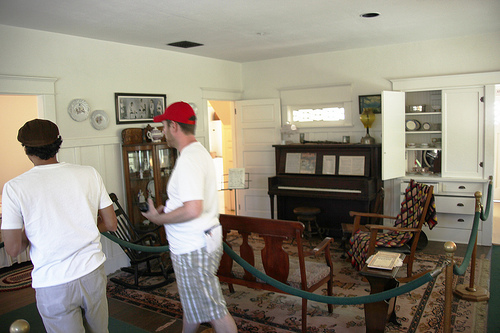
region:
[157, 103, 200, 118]
man has on a red hat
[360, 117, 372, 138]
yellow glass cup on top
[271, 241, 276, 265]
bench is made out of wood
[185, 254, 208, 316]
man wearing some checker shorts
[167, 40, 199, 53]
air vent in the ceiling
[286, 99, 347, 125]
window behind the wooden door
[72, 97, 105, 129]
plates are hanging on the wall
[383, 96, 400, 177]
door to the cabinet is open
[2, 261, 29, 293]
rug is on the floor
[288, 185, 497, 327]
green velvet rope around furniture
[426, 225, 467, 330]
wood posts with gold tops holding rope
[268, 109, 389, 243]
vintage upright piano with stool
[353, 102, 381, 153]
vintage yellow glass kerosene lamp on piano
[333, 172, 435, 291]
wood rocking chair with knitted blanket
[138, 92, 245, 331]
man in red cap and plaid shorts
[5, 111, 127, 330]
back of man in brown hat and white shirt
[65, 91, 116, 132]
vintage china plates hanging on white wall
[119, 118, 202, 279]
wood curio cabinet with glass doors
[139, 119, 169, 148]
vintage china tea kettle with pattern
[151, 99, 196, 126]
man wearing a red cap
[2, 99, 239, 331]
two men standing in a living room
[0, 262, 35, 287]
an oval rug on the floor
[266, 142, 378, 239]
a dark wooden upright piano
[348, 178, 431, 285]
a wooden rocking chair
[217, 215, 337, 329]
a wooden bench with gray cushion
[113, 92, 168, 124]
a framed picture on the wall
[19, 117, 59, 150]
man wearing a round brown hat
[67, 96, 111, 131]
decorative white plates on the wall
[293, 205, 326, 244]
a wooden piano stool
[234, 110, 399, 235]
a brown piano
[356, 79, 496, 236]
a white cupboard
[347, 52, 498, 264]
a white cupboard with dishes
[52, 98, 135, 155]
white plates on the wall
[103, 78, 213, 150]
a picture frame on the wall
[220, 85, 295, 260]
a white wooden door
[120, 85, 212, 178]
a man with a red hat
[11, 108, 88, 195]
a man wearing a brown hat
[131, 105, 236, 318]
a man wearing plaid shorts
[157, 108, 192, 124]
red baseball cap on man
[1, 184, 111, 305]
white t shirt on man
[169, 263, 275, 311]
grey and white shorts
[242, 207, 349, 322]
brown bench with tan cushion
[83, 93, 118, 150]
two plates on the wall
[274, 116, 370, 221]
black piano with mic sheets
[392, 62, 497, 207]
white cabinets on the wall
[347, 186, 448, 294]
colorful blanket on the rocker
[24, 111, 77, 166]
man with brown hat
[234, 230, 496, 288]
green rope on sticks